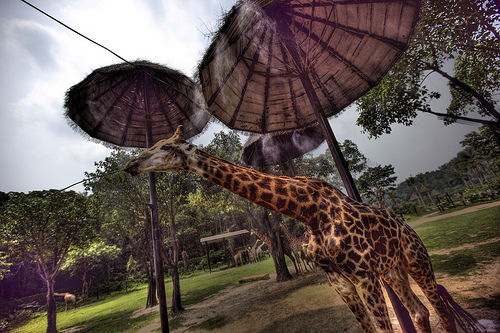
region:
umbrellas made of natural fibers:
[47, 12, 402, 158]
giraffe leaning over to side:
[106, 122, 431, 297]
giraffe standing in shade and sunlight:
[115, 130, 460, 315]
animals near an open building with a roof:
[196, 220, 263, 275]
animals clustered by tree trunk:
[255, 210, 315, 275]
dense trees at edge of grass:
[21, 152, 261, 294]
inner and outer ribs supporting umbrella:
[215, 10, 400, 125]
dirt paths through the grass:
[160, 250, 485, 315]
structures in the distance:
[425, 167, 487, 223]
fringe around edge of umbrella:
[57, 62, 138, 158]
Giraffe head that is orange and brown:
[97, 127, 234, 189]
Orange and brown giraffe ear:
[171, 119, 196, 146]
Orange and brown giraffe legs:
[294, 233, 479, 331]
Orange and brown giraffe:
[91, 110, 463, 330]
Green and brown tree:
[17, 192, 123, 319]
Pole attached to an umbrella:
[131, 146, 207, 331]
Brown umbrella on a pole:
[56, 41, 224, 161]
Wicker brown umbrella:
[64, 52, 243, 185]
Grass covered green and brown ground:
[408, 215, 496, 242]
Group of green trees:
[385, 153, 497, 195]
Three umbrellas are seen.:
[51, 15, 373, 115]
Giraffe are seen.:
[142, 137, 474, 323]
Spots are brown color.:
[305, 197, 376, 262]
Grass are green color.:
[66, 305, 117, 321]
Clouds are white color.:
[15, 27, 71, 80]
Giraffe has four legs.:
[310, 270, 453, 330]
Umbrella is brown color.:
[65, 20, 335, 150]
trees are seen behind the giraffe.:
[5, 178, 491, 213]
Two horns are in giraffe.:
[167, 122, 185, 138]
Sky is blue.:
[380, 131, 457, 158]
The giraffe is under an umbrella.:
[117, 124, 479, 331]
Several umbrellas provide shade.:
[57, 0, 428, 176]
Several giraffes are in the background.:
[222, 219, 324, 279]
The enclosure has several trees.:
[0, 131, 239, 331]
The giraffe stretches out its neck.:
[99, 120, 350, 222]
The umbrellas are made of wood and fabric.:
[58, 0, 461, 198]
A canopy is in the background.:
[195, 222, 256, 277]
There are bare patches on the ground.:
[156, 262, 321, 332]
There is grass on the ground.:
[0, 268, 194, 331]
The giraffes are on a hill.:
[0, 147, 497, 331]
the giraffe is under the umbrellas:
[126, 127, 487, 329]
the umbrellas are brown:
[65, 0, 426, 162]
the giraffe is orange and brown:
[127, 127, 478, 329]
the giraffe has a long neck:
[194, 150, 329, 221]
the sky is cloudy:
[2, 4, 498, 194]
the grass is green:
[0, 199, 499, 323]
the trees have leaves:
[1, 2, 499, 282]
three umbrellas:
[66, 0, 425, 169]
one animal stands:
[128, 125, 485, 330]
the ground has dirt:
[0, 199, 499, 329]